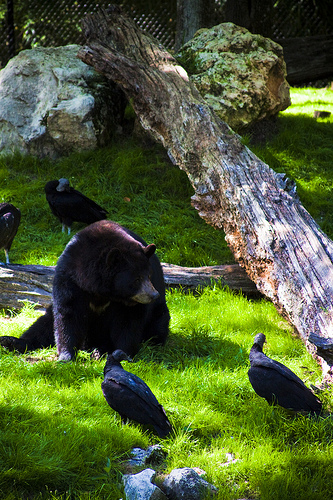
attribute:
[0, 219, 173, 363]
bear — standing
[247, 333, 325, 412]
bird — standing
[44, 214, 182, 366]
bear — dark, large, standing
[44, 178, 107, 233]
birds — standing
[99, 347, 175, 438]
birds — standing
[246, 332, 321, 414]
birds — standing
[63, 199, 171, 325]
bear — large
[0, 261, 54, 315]
structure — wood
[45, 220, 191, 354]
bear — standing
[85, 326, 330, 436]
birds — standing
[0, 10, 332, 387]
tree — dead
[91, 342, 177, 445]
bird — standing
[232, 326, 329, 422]
bird — standing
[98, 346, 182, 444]
bird — standing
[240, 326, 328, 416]
bird — standing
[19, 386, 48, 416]
grass — green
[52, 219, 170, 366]
hair — dark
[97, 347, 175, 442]
bird — standing